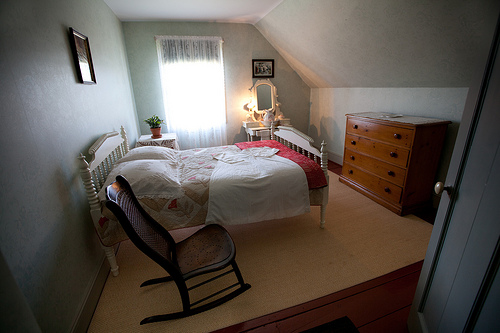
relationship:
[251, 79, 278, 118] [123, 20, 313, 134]
mirror against wall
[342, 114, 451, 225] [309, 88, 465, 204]
dresser against wall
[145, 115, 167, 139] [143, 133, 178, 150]
flower pot on table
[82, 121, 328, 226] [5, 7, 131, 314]
bed against wall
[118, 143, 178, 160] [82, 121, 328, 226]
pillow on bed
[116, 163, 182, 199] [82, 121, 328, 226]
pillow on bed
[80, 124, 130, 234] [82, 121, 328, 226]
headboard on bed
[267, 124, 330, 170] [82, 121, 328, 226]
footboard on bed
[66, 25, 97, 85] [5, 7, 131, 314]
picture hangs on wall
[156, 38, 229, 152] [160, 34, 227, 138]
curtains cover window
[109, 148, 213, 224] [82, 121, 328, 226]
quilt in bed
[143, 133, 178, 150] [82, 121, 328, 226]
table beside bed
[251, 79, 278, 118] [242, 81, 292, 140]
mirror on a vanity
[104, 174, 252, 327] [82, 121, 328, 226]
rocker by bed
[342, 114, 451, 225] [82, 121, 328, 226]
dresser in front of bed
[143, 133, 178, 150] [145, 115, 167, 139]
table with flower pot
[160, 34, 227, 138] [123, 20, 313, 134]
window on far wall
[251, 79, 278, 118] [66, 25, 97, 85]
mirror under picture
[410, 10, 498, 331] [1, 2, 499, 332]
door to bedroom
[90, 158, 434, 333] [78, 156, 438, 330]
carpet on floor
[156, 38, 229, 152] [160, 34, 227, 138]
curtains hang in window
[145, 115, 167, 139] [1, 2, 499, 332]
flower pot in bedroom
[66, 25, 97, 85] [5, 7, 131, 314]
picture on a wall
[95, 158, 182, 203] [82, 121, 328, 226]
pillow on bed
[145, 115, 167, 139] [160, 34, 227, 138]
flower pot near window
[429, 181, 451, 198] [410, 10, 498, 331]
doorknob on door